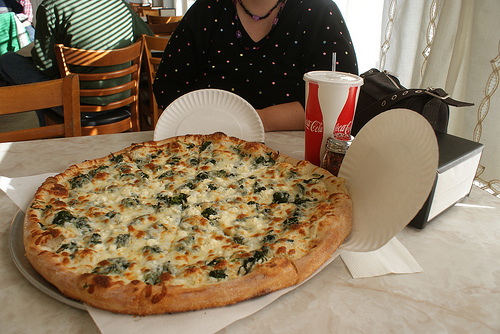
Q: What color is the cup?
A: Red and white.